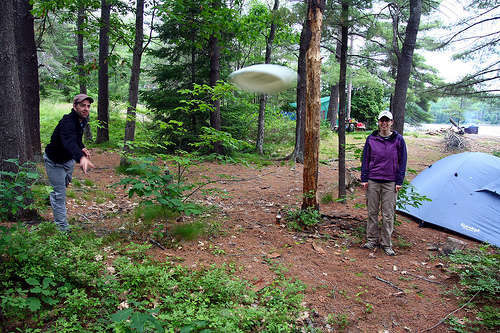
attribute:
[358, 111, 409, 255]
woman — smiling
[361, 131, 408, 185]
jacket — purple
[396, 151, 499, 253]
tent — blue, large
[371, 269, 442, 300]
twigs — dry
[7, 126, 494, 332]
ground — brown, dirty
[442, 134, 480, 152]
branches — in a pile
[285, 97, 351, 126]
shack — green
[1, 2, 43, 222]
tree trunk — brown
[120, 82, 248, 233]
tree — green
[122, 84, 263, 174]
leaves — green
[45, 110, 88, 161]
coat — black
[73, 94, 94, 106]
cap — brown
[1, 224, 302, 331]
plants — green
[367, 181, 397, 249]
pants — gray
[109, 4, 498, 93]
sky — white, clear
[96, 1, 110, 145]
tree — tall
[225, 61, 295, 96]
frisbee — white, in air